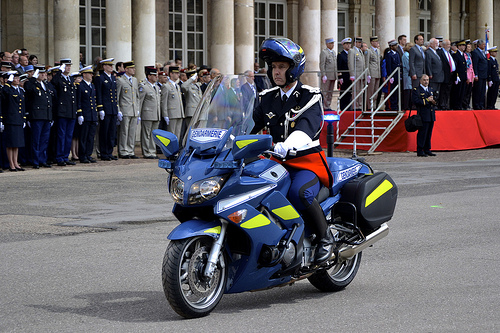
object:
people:
[365, 35, 381, 111]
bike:
[152, 74, 400, 321]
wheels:
[161, 234, 230, 321]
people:
[384, 40, 406, 111]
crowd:
[0, 52, 221, 170]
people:
[408, 34, 432, 90]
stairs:
[325, 67, 407, 152]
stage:
[332, 109, 500, 150]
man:
[336, 37, 352, 111]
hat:
[342, 37, 353, 44]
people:
[2, 70, 31, 172]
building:
[3, 0, 497, 172]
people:
[318, 38, 335, 111]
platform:
[320, 106, 499, 152]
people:
[347, 37, 369, 112]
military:
[0, 48, 120, 171]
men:
[116, 61, 142, 157]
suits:
[114, 73, 139, 155]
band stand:
[323, 110, 484, 148]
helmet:
[258, 34, 307, 83]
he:
[245, 36, 338, 265]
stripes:
[198, 175, 397, 235]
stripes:
[235, 134, 264, 148]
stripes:
[153, 130, 171, 146]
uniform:
[2, 80, 30, 147]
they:
[320, 33, 500, 109]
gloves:
[272, 129, 312, 157]